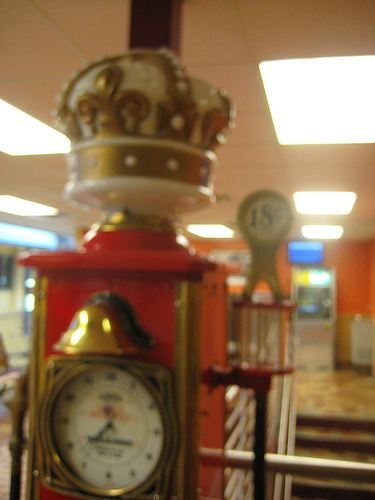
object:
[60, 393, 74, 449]
numbers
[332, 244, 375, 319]
orange wall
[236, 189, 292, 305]
sign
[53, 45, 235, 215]
crown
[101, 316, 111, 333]
shine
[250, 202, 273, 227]
number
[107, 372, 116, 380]
numbers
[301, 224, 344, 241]
light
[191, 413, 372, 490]
railing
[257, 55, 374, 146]
light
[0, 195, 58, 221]
light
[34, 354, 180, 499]
clock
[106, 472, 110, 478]
numbers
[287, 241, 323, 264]
monitor screen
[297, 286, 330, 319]
screen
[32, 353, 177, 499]
gold circle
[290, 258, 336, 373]
doorway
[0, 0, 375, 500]
room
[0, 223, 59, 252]
light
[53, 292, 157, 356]
bell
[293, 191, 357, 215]
light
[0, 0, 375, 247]
ceiling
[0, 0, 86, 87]
tile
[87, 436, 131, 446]
black writing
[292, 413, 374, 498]
staircase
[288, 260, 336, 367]
door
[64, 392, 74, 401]
numbers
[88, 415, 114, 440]
black hand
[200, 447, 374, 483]
rail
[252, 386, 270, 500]
pole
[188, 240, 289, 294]
wall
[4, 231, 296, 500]
candy machine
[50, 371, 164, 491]
face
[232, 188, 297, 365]
post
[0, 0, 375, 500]
store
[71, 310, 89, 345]
light